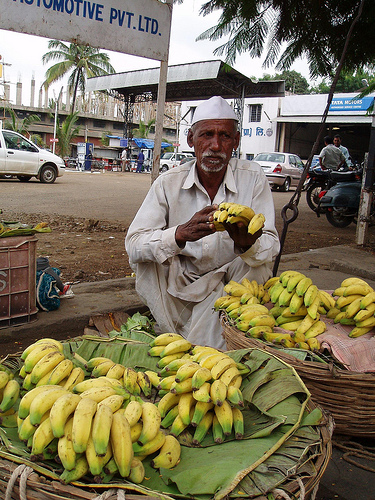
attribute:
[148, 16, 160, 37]
letter — blue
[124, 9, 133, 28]
letter — blue